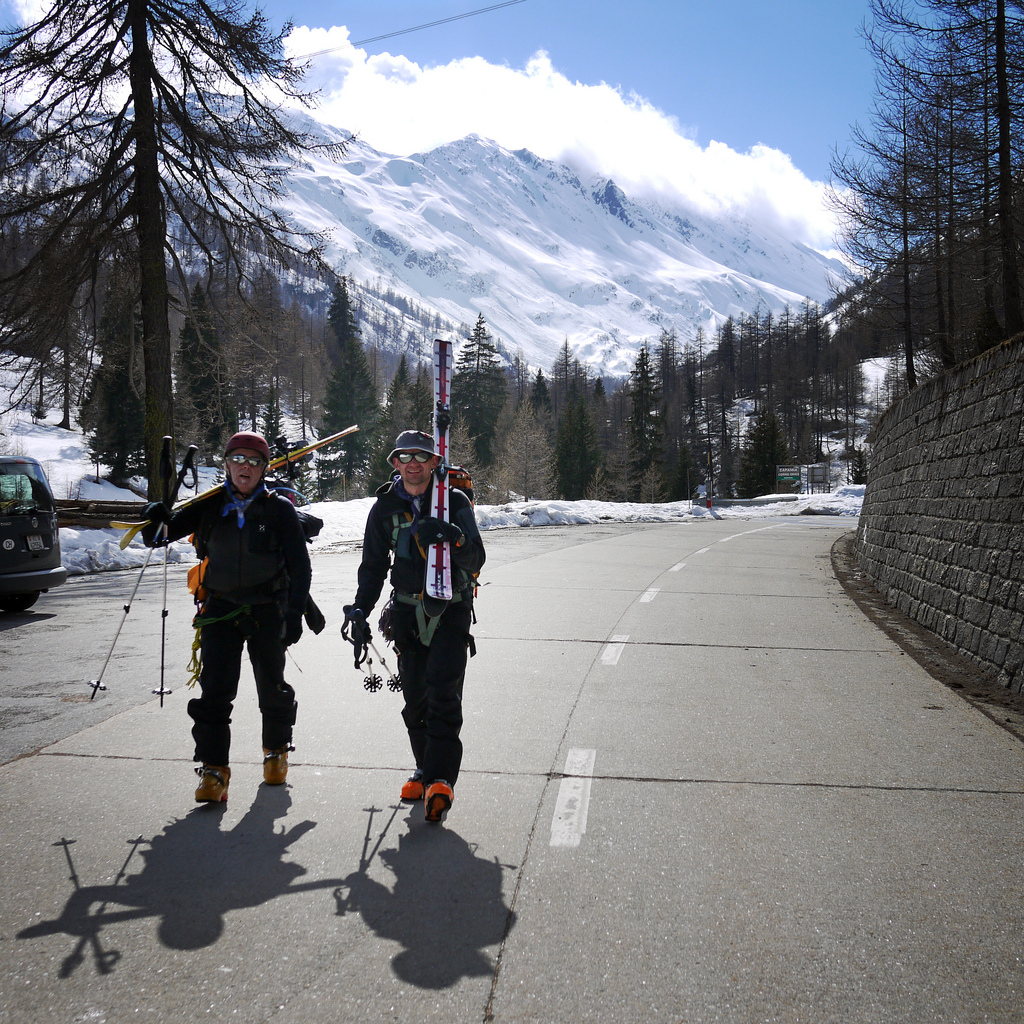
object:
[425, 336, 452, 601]
ski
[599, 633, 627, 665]
stripe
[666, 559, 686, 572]
stripe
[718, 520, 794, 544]
stripe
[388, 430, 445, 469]
hat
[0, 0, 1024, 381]
clouds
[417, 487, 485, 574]
arm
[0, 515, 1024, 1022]
street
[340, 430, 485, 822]
man